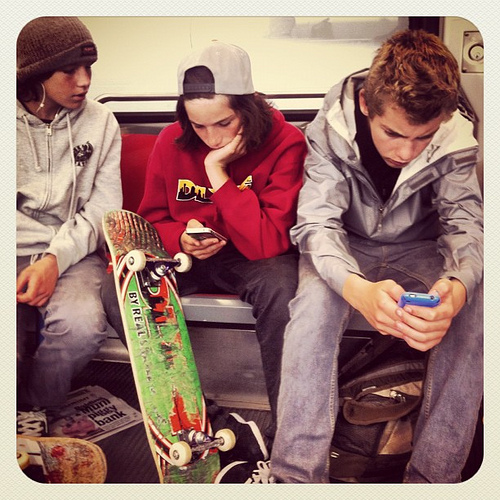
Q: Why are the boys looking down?
A: Phones.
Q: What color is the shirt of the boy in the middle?
A: Red.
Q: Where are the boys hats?
A: On their heads.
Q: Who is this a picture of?
A: 3 boys.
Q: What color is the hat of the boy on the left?
A: Brown.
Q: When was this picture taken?
A: Daytime.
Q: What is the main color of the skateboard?
A: Green.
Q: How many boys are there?
A: Three.